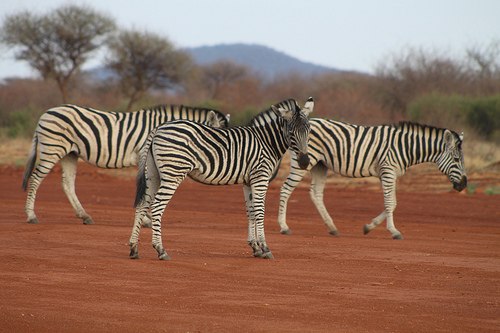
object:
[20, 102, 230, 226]
zebra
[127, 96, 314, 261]
zebra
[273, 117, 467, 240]
zebra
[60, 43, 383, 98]
hill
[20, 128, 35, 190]
tail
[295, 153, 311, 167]
snout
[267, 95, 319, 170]
head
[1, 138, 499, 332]
ground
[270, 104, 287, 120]
ear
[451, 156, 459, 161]
eye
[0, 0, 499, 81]
sky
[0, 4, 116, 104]
tree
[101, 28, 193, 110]
tree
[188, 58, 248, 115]
tree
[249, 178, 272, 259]
front leg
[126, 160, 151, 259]
hind leg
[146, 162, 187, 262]
hind leg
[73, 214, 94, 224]
hoof